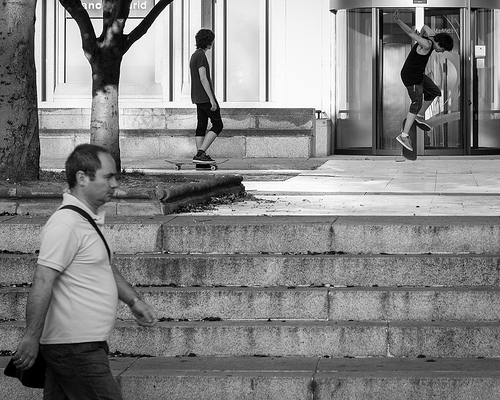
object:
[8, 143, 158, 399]
man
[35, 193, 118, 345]
shirt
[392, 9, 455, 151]
boy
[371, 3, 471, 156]
door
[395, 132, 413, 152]
foot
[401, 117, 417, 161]
skateboard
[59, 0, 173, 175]
tree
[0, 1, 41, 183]
trees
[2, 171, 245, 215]
planter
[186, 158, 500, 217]
sidewalk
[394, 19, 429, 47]
arms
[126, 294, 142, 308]
watch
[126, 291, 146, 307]
wrist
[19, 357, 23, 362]
ring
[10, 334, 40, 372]
hand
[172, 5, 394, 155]
building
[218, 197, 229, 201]
leaves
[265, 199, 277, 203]
dirt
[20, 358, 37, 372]
finger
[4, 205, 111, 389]
bag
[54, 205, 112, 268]
strap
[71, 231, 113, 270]
chest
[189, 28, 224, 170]
boy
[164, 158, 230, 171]
skateboard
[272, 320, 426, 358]
stairs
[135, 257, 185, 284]
markings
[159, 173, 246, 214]
corners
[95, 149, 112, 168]
hairline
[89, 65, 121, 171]
trunk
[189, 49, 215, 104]
t-shirt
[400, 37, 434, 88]
tank top